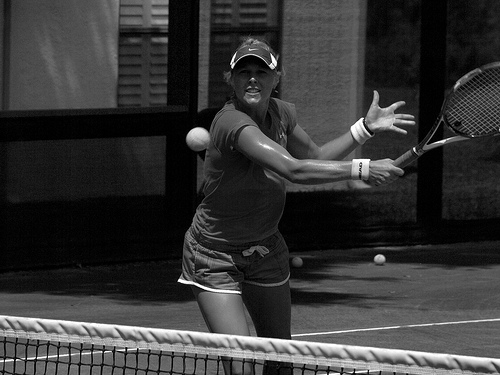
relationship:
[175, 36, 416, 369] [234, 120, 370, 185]
woman has arm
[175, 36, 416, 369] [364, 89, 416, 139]
woman has hand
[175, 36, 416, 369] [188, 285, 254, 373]
woman has leg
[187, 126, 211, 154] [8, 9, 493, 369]
ball for tennis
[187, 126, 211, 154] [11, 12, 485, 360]
ball in air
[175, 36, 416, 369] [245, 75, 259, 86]
woman has nose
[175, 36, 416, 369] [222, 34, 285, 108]
woman has head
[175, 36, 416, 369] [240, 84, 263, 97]
woman has mouth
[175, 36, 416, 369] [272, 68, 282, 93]
woman has ear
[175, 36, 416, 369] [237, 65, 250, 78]
woman has eye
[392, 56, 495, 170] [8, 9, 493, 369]
racket for tennis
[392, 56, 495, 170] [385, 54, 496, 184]
racket does exist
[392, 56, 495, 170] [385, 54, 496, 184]
racket has visibility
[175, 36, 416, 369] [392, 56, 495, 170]
woman holding racket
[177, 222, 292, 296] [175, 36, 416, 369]
shorts on woman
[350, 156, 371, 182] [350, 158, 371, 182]
band for wrist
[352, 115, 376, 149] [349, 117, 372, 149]
band for wrist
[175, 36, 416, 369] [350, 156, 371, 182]
woman wearing band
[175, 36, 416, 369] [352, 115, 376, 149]
woman wearing band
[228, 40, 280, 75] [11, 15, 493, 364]
visor for sun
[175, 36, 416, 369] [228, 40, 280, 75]
woman wearing visor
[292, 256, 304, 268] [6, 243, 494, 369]
balls on top of ground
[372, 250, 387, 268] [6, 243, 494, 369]
ball on top of ground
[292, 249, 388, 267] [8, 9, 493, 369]
balls are for tennis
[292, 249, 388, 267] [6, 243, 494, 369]
balls on top of ground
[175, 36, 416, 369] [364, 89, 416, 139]
woman with hand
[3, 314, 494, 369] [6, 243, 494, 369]
net for court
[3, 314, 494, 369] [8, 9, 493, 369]
net for tennis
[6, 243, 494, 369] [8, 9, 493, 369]
court for tennis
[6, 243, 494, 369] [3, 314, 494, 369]
court for net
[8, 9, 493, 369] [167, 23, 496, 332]
tennis being played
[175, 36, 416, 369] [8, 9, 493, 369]
woman in tennis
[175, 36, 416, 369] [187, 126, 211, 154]
woman looking at ball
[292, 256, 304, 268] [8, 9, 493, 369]
balls for tennis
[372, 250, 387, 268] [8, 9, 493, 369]
ball for tennis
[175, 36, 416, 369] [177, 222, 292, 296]
woman in shorts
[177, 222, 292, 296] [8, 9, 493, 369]
shorts for tennis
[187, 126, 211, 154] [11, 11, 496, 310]
ball in mid-air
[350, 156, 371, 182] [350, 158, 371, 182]
wristband for wrist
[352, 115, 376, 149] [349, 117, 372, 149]
wristband for wrist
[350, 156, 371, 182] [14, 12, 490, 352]
wristband for sports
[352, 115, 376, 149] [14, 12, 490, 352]
wristband for sports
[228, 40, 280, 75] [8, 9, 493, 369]
visor for tennis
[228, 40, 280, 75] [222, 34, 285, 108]
visor being worn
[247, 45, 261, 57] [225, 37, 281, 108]
nike being worn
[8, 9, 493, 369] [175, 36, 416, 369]
tennis played by woman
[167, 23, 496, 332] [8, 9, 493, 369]
playing of tennis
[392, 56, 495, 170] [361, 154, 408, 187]
racket being held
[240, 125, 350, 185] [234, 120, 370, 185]
sweat on arm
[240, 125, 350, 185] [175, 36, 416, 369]
sweat on woman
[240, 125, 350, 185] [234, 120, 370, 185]
sweat on top of arm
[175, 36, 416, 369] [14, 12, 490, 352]
woman playing sports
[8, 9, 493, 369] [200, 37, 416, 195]
sport played intensely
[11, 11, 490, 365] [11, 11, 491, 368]
black in picture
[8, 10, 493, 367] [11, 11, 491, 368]
white in picture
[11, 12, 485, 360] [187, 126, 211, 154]
air around ball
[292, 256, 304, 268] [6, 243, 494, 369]
balls on ground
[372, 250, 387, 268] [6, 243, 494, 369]
ball on ground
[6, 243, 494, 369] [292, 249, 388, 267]
ground has balls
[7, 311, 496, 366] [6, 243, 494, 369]
line on top of ground